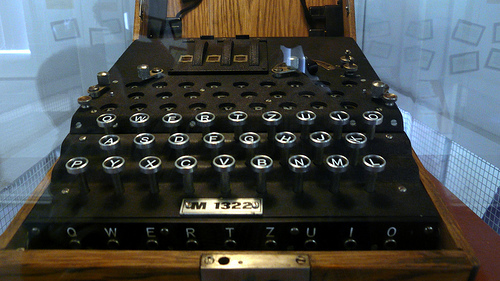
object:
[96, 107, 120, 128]
key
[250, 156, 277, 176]
key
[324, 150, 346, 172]
keys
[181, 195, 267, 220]
plate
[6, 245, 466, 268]
edge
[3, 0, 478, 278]
box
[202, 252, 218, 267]
screw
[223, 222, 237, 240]
t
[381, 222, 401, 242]
o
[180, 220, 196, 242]
r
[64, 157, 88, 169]
alphabet letter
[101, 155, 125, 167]
alphabet letter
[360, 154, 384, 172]
alphabet letter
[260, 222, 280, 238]
alphabet letter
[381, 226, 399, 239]
alphabet letter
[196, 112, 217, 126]
alphabet letter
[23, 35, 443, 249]
machine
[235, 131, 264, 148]
alphabet letter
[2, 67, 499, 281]
desk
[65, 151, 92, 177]
p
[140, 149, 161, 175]
x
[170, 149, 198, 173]
c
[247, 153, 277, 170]
b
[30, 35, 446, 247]
typewriter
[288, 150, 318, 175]
n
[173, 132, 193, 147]
d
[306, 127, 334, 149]
j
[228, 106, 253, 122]
t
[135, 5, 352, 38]
cabinet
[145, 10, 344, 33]
stripes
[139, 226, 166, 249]
letters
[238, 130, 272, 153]
knobs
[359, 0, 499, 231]
curtains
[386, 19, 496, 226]
wall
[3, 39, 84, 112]
wall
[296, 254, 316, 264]
screw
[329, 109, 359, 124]
keys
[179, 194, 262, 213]
numbers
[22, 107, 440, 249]
board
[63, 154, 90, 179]
key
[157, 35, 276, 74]
squares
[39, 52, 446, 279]
frame